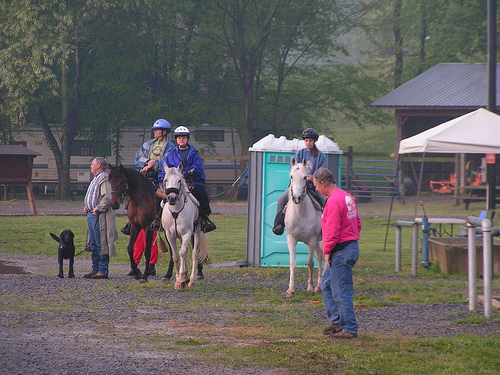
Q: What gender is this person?
A: Male.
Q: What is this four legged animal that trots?
A: Horse.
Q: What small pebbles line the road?
A: Gravel.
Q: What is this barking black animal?
A: Dog.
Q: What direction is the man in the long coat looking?
A: Left.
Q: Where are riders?
A: On back of horses.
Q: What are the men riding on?
A: Horses.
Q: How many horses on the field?
A: Three.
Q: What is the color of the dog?
A: Black.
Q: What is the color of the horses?
A: White and brown.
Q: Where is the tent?
A: Beside bathroom.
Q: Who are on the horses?
A: People.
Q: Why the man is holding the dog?
A: So it won't runaway.